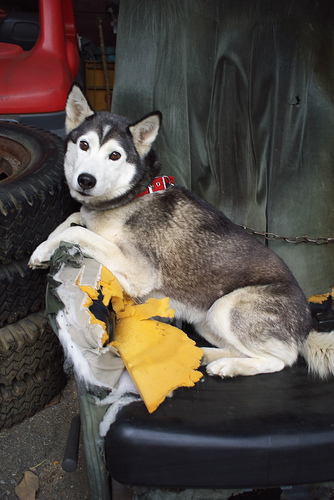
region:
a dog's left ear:
[128, 109, 159, 157]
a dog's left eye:
[108, 146, 122, 160]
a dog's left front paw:
[23, 238, 62, 267]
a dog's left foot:
[204, 355, 285, 377]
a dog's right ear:
[61, 84, 94, 129]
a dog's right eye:
[80, 138, 89, 153]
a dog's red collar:
[131, 172, 175, 199]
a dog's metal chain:
[242, 182, 332, 243]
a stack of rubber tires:
[1, 119, 62, 430]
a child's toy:
[1, 1, 82, 118]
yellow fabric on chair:
[94, 299, 183, 385]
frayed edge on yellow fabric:
[147, 390, 173, 410]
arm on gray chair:
[54, 410, 88, 492]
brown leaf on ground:
[2, 472, 54, 498]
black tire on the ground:
[20, 187, 52, 222]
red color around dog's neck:
[128, 173, 177, 197]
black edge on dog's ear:
[124, 113, 168, 138]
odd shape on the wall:
[190, 50, 291, 202]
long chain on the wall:
[202, 205, 331, 256]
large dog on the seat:
[59, 98, 296, 332]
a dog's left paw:
[30, 237, 60, 270]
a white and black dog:
[27, 84, 332, 380]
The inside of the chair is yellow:
[112, 308, 190, 389]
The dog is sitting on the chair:
[24, 81, 333, 394]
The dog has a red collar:
[142, 172, 184, 199]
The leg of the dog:
[24, 229, 158, 300]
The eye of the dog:
[107, 146, 126, 166]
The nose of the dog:
[77, 170, 98, 190]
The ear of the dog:
[122, 104, 167, 161]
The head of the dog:
[60, 81, 164, 207]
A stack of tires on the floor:
[0, 95, 71, 428]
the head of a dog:
[50, 83, 196, 220]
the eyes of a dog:
[67, 126, 154, 170]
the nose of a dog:
[67, 155, 111, 196]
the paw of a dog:
[23, 232, 80, 277]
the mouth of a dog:
[54, 165, 115, 215]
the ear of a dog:
[115, 84, 190, 155]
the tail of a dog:
[292, 320, 333, 379]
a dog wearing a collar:
[85, 149, 211, 217]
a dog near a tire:
[5, 76, 213, 371]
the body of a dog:
[62, 147, 327, 399]